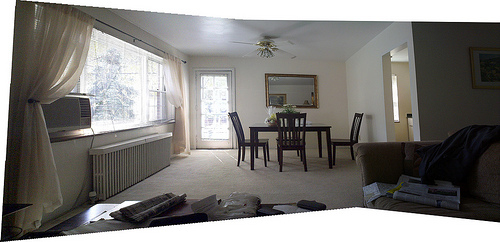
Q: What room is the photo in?
A: It is at the kitchen.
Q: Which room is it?
A: It is a kitchen.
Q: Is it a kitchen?
A: Yes, it is a kitchen.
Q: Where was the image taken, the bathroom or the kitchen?
A: It was taken at the kitchen.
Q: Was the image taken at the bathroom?
A: No, the picture was taken in the kitchen.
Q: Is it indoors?
A: Yes, it is indoors.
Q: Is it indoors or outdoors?
A: It is indoors.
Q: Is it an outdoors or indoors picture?
A: It is indoors.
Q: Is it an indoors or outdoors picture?
A: It is indoors.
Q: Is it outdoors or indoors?
A: It is indoors.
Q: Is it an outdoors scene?
A: No, it is indoors.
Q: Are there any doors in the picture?
A: Yes, there is a door.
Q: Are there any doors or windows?
A: Yes, there is a door.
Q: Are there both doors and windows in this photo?
A: Yes, there are both a door and a window.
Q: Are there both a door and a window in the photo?
A: Yes, there are both a door and a window.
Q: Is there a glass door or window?
A: Yes, there is a glass door.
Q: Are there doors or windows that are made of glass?
A: Yes, the door is made of glass.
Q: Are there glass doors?
A: Yes, there is a door that is made of glass.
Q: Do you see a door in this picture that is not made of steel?
A: Yes, there is a door that is made of glass.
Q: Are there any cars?
A: No, there are no cars.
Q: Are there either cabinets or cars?
A: No, there are no cars or cabinets.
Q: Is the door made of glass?
A: Yes, the door is made of glass.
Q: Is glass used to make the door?
A: Yes, the door is made of glass.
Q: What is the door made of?
A: The door is made of glass.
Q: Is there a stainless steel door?
A: No, there is a door but it is made of glass.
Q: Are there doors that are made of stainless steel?
A: No, there is a door but it is made of glass.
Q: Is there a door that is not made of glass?
A: No, there is a door but it is made of glass.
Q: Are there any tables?
A: Yes, there is a table.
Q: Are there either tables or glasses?
A: Yes, there is a table.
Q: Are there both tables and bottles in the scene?
A: No, there is a table but no bottles.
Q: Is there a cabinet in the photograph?
A: No, there are no cabinets.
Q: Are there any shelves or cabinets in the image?
A: No, there are no cabinets or shelves.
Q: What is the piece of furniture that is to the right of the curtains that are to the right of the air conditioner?
A: The piece of furniture is a table.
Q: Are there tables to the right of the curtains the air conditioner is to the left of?
A: Yes, there is a table to the right of the curtains.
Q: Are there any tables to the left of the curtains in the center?
A: No, the table is to the right of the curtains.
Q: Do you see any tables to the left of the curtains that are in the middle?
A: No, the table is to the right of the curtains.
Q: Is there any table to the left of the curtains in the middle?
A: No, the table is to the right of the curtains.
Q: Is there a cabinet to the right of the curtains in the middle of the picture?
A: No, there is a table to the right of the curtains.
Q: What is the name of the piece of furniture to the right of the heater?
A: The piece of furniture is a table.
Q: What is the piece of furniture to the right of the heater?
A: The piece of furniture is a table.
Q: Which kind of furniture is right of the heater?
A: The piece of furniture is a table.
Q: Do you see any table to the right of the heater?
A: Yes, there is a table to the right of the heater.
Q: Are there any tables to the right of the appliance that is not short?
A: Yes, there is a table to the right of the heater.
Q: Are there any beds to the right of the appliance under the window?
A: No, there is a table to the right of the heater.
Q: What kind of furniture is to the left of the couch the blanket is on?
A: The piece of furniture is a table.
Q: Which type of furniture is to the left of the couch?
A: The piece of furniture is a table.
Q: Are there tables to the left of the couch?
A: Yes, there is a table to the left of the couch.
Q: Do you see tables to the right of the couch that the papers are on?
A: No, the table is to the left of the couch.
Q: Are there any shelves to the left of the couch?
A: No, there is a table to the left of the couch.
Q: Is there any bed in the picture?
A: No, there are no beds.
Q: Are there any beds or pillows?
A: No, there are no beds or pillows.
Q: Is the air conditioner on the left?
A: Yes, the air conditioner is on the left of the image.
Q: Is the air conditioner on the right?
A: No, the air conditioner is on the left of the image.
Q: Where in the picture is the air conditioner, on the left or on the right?
A: The air conditioner is on the left of the image.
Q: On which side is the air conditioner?
A: The air conditioner is on the left of the image.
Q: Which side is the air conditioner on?
A: The air conditioner is on the left of the image.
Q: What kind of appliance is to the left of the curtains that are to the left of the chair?
A: The appliance is an air conditioner.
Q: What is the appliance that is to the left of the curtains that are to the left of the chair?
A: The appliance is an air conditioner.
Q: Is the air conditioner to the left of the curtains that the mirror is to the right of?
A: Yes, the air conditioner is to the left of the curtains.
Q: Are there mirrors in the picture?
A: Yes, there is a mirror.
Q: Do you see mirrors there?
A: Yes, there is a mirror.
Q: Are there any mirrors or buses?
A: Yes, there is a mirror.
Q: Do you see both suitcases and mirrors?
A: No, there is a mirror but no suitcases.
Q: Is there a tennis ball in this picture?
A: No, there are no tennis balls.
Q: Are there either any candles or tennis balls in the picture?
A: No, there are no tennis balls or candles.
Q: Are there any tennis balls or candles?
A: No, there are no tennis balls or candles.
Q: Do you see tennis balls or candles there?
A: No, there are no tennis balls or candles.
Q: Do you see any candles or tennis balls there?
A: No, there are no tennis balls or candles.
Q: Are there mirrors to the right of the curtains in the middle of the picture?
A: Yes, there is a mirror to the right of the curtains.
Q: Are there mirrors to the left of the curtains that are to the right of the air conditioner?
A: No, the mirror is to the right of the curtains.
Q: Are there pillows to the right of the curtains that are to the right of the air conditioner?
A: No, there is a mirror to the right of the curtains.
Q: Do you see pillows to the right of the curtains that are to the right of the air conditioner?
A: No, there is a mirror to the right of the curtains.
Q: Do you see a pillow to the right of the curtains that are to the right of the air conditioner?
A: No, there is a mirror to the right of the curtains.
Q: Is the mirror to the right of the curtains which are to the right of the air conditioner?
A: Yes, the mirror is to the right of the curtains.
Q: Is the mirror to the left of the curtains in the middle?
A: No, the mirror is to the right of the curtains.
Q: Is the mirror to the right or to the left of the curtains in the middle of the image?
A: The mirror is to the right of the curtains.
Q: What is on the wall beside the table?
A: The mirror is on the wall.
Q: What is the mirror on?
A: The mirror is on the wall.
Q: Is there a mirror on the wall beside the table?
A: Yes, there is a mirror on the wall.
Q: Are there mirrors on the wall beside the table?
A: Yes, there is a mirror on the wall.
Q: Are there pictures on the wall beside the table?
A: No, there is a mirror on the wall.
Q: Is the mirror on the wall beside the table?
A: Yes, the mirror is on the wall.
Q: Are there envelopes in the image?
A: No, there are no envelopes.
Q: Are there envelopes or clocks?
A: No, there are no envelopes or clocks.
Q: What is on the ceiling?
A: The fan is on the ceiling.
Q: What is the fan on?
A: The fan is on the ceiling.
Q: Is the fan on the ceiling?
A: Yes, the fan is on the ceiling.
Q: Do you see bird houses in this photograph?
A: No, there are no bird houses.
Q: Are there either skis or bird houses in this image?
A: No, there are no bird houses or skis.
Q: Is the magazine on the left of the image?
A: Yes, the magazine is on the left of the image.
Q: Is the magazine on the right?
A: No, the magazine is on the left of the image.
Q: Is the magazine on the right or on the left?
A: The magazine is on the left of the image.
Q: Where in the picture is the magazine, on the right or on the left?
A: The magazine is on the left of the image.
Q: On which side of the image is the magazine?
A: The magazine is on the left of the image.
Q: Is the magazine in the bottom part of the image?
A: Yes, the magazine is in the bottom of the image.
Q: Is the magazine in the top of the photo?
A: No, the magazine is in the bottom of the image.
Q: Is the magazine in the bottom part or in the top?
A: The magazine is in the bottom of the image.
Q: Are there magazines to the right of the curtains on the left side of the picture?
A: Yes, there is a magazine to the right of the curtains.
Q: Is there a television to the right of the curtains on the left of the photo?
A: No, there is a magazine to the right of the curtains.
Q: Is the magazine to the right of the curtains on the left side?
A: Yes, the magazine is to the right of the curtains.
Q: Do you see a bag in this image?
A: No, there are no bags.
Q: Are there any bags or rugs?
A: No, there are no bags or rugs.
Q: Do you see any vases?
A: No, there are no vases.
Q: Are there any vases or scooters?
A: No, there are no vases or scooters.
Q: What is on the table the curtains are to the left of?
A: The flowers are on the table.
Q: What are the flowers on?
A: The flowers are on the table.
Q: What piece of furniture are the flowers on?
A: The flowers are on the table.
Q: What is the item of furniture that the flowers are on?
A: The piece of furniture is a table.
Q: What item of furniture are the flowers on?
A: The flowers are on the table.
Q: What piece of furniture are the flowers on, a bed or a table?
A: The flowers are on a table.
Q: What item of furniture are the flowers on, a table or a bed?
A: The flowers are on a table.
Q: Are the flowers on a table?
A: Yes, the flowers are on a table.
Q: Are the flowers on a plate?
A: No, the flowers are on a table.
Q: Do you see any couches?
A: Yes, there is a couch.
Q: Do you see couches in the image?
A: Yes, there is a couch.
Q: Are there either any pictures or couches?
A: Yes, there is a couch.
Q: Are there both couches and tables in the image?
A: Yes, there are both a couch and a table.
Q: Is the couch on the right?
A: Yes, the couch is on the right of the image.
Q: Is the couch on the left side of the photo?
A: No, the couch is on the right of the image.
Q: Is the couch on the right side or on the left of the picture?
A: The couch is on the right of the image.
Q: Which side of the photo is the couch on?
A: The couch is on the right of the image.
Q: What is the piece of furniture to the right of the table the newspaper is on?
A: The piece of furniture is a couch.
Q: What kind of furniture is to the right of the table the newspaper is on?
A: The piece of furniture is a couch.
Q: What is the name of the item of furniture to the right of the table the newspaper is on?
A: The piece of furniture is a couch.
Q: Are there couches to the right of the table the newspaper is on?
A: Yes, there is a couch to the right of the table.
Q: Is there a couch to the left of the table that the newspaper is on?
A: No, the couch is to the right of the table.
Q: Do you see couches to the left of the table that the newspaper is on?
A: No, the couch is to the right of the table.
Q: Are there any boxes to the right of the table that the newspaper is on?
A: No, there is a couch to the right of the table.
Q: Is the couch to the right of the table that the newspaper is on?
A: Yes, the couch is to the right of the table.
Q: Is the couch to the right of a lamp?
A: No, the couch is to the right of the table.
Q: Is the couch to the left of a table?
A: No, the couch is to the right of a table.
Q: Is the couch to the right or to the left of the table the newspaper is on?
A: The couch is to the right of the table.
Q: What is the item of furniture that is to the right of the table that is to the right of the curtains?
A: The piece of furniture is a couch.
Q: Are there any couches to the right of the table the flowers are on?
A: Yes, there is a couch to the right of the table.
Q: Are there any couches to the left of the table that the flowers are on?
A: No, the couch is to the right of the table.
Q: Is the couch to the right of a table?
A: Yes, the couch is to the right of a table.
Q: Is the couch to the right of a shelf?
A: No, the couch is to the right of a table.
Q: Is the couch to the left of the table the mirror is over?
A: No, the couch is to the right of the table.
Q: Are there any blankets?
A: Yes, there is a blanket.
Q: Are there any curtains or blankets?
A: Yes, there is a blanket.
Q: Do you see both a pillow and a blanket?
A: No, there is a blanket but no pillows.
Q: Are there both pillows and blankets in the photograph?
A: No, there is a blanket but no pillows.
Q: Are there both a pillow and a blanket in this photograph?
A: No, there is a blanket but no pillows.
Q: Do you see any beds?
A: No, there are no beds.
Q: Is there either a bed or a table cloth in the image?
A: No, there are no beds or tablecloths.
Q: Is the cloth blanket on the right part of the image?
A: Yes, the blanket is on the right of the image.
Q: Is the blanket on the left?
A: No, the blanket is on the right of the image.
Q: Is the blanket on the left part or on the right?
A: The blanket is on the right of the image.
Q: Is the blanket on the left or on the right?
A: The blanket is on the right of the image.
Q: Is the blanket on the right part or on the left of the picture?
A: The blanket is on the right of the image.